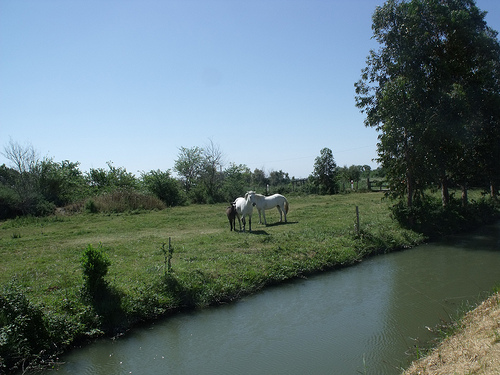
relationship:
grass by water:
[407, 287, 499, 373] [17, 225, 497, 373]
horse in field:
[250, 185, 295, 226] [30, 200, 420, 341]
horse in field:
[219, 184, 259, 235] [30, 200, 420, 341]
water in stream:
[267, 298, 370, 373] [37, 217, 498, 373]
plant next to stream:
[160, 241, 167, 273] [37, 217, 498, 373]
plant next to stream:
[0, 243, 190, 347] [37, 217, 498, 373]